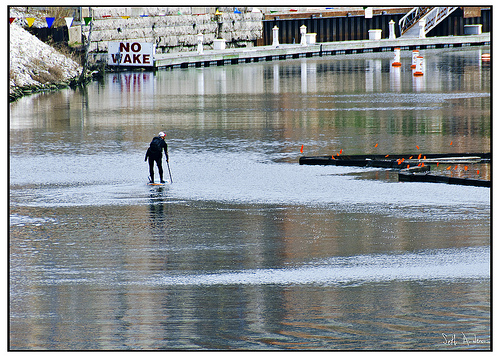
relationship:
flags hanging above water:
[17, 8, 262, 47] [153, 60, 356, 178]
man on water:
[136, 124, 172, 190] [169, 172, 224, 204]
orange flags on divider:
[287, 131, 484, 178] [295, 152, 492, 195]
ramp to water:
[390, 4, 455, 46] [1, 43, 496, 351]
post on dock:
[270, 24, 279, 47] [153, 32, 490, 70]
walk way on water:
[133, 28, 485, 65] [98, 42, 498, 295]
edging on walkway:
[95, 38, 492, 73] [127, 32, 491, 70]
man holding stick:
[136, 124, 172, 190] [166, 159, 174, 181]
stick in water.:
[166, 159, 174, 181] [145, 189, 322, 273]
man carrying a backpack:
[136, 124, 172, 190] [148, 134, 163, 154]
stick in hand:
[166, 159, 174, 181] [164, 153, 170, 161]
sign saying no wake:
[78, 43, 182, 68] [109, 39, 159, 73]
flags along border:
[295, 136, 498, 178] [311, 150, 416, 179]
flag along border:
[409, 141, 419, 153] [311, 150, 416, 179]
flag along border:
[286, 135, 316, 159] [311, 150, 416, 179]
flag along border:
[444, 155, 456, 174] [311, 150, 416, 179]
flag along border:
[393, 151, 407, 171] [311, 150, 416, 179]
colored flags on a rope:
[11, 13, 88, 31] [9, 10, 325, 26]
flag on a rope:
[38, 14, 58, 33] [9, 10, 325, 26]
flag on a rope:
[22, 16, 42, 29] [9, 10, 325, 26]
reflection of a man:
[131, 178, 191, 235] [139, 131, 170, 183]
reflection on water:
[131, 178, 191, 235] [170, 240, 328, 318]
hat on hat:
[155, 132, 166, 141] [155, 132, 166, 141]